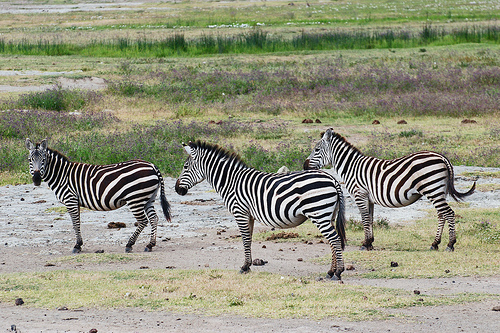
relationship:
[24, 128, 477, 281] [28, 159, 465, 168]
zebras are standing in a line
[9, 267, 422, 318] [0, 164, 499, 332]
grass in dirt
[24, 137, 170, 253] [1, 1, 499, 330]
zebra standing in a field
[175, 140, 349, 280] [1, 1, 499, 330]
zebra standing in a field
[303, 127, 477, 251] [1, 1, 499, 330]
zebra standing in a field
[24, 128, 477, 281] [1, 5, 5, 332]
zebras are facing to right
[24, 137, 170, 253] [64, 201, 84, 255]
zebra has front legs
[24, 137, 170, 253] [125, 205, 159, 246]
zebra has back legs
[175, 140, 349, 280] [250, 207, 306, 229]
zebra has a belly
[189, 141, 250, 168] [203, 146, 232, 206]
mane above neck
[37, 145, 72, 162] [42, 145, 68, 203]
mane above neck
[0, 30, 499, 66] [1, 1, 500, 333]
grass on field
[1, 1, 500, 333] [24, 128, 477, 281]
field underneath zebras